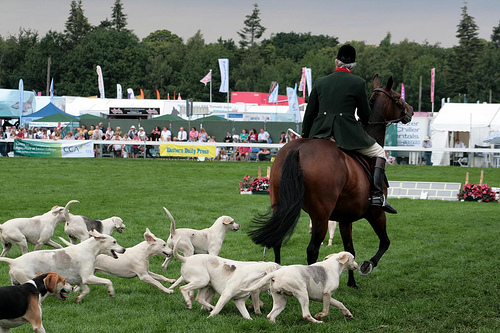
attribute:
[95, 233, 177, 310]
dog — white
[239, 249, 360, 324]
dog — white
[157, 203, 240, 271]
dog — white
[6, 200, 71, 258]
dog — white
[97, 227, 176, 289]
dog — white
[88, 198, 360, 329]
dogs — white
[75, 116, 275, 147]
crownd — Large  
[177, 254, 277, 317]
dog — white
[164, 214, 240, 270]
dog — white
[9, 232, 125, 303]
dog — white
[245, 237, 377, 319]
dog — white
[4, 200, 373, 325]
dog — white, brown, black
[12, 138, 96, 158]
banner — green, white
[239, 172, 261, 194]
flowers — pink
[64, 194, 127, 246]
dog — white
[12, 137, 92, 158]
banners — vinyl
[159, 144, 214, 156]
banners — vinyl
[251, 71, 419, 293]
horse — brown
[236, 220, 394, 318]
dog — white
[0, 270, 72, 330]
dog — white, brown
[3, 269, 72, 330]
beagle — brown , Black 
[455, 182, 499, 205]
flowers — ARE PINK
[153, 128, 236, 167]
banner — yellow, blue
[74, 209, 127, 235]
white dog — White 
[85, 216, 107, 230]
black spot — black 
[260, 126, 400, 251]
brown horse — brown 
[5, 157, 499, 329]
turf — Large green, horse park.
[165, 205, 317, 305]
dog — white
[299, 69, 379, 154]
jacket — black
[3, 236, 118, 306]
dog — white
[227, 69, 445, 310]
horse — dark brown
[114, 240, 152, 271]
fur — black 